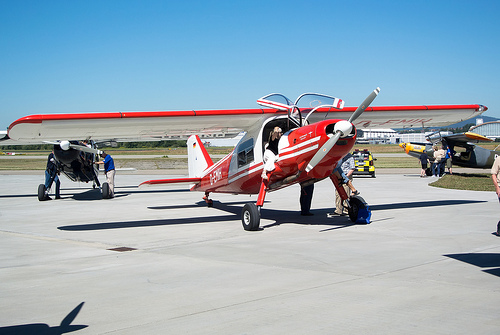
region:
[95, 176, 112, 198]
the wheel of a plane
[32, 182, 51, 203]
the wheel of a plane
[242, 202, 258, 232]
the wheel of a plane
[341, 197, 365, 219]
the wheel of a plane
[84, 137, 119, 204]
a person in the airport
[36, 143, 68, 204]
a person in the airport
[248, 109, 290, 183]
a person in the airport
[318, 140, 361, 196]
a person in the airport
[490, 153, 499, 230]
a person in the airport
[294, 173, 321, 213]
a person in the airport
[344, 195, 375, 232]
the wheel of a plane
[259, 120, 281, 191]
a person in the airport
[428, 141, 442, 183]
a person in the airport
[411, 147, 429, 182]
a person in the airport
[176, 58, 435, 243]
the airplane is red and white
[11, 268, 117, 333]
shadow of an airplane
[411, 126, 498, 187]
people standing next to a plane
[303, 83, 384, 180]
the propeller of the plane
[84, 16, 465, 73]
the sky is blue and clear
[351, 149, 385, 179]
the car is yellow and black checkered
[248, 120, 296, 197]
person in the plane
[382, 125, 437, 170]
the nose of the plane is yellow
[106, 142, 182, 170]
runway for the airplanes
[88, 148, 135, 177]
man is wearing a blue shirt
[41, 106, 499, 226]
An airport for planes.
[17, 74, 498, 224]
Three airplanes that are being looked at by people.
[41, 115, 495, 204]
Many people looking at airplanes.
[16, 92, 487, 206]
A red and white airplane.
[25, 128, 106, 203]
A black and blue airplane.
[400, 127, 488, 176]
A yellow, gray and black airplane.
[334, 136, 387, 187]
A black and yellow vehicle.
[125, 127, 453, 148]
A large white building in the distance.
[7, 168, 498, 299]
A large cement area for the planes to park.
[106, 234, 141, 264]
A grate above a hole for water to flow into.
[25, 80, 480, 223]
A red and white prop plane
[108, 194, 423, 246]
The shadow of a plane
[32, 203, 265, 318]
A large concreted area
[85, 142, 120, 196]
A man reaching for a plane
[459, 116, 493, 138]
A plane hangar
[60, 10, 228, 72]
A cloudless blue sky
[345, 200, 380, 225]
A blue wheel chock keeping a plane from moving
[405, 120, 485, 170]
A grey and yellow airplane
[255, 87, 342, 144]
Two open doors on a plane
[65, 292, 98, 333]
The shadow of a propeller